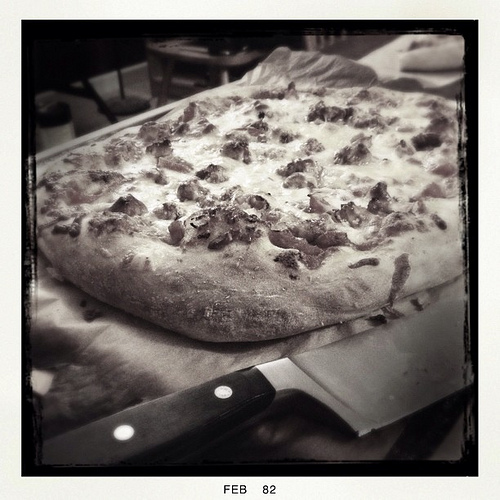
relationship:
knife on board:
[31, 285, 469, 480] [29, 49, 476, 478]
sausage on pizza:
[270, 228, 322, 266] [26, 79, 469, 348]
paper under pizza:
[231, 45, 384, 89] [26, 79, 469, 348]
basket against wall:
[32, 97, 77, 154] [32, 34, 263, 132]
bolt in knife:
[213, 385, 237, 399] [31, 285, 469, 480]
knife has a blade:
[31, 285, 469, 480] [293, 274, 475, 437]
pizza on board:
[26, 79, 469, 348] [29, 49, 476, 478]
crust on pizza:
[30, 198, 465, 348] [26, 79, 469, 348]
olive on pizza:
[411, 131, 442, 154] [26, 79, 469, 348]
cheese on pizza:
[234, 161, 277, 189] [26, 79, 469, 348]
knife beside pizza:
[31, 285, 469, 480] [26, 79, 469, 348]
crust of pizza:
[30, 198, 465, 348] [26, 79, 469, 348]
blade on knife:
[293, 274, 475, 437] [31, 285, 469, 480]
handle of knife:
[30, 363, 280, 472] [31, 285, 469, 480]